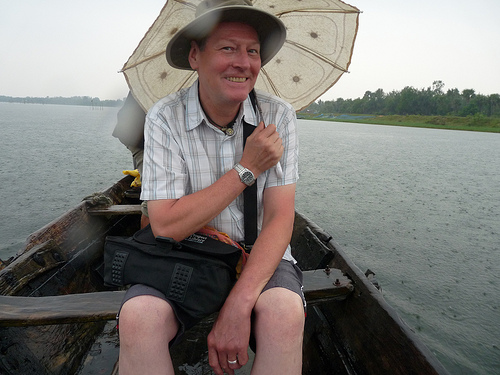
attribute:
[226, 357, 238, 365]
ring — for wedding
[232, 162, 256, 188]
watch — for wrist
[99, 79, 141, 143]
droplet — water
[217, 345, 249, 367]
ring — for wedding